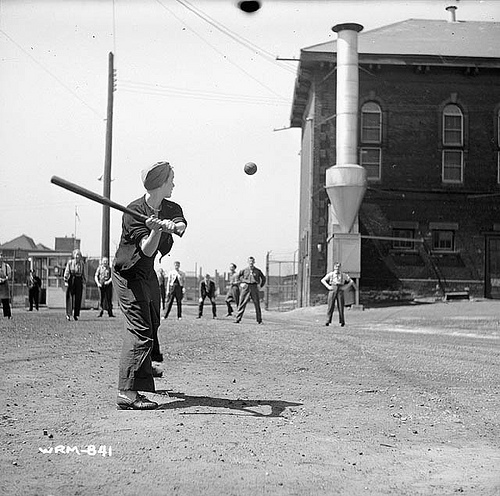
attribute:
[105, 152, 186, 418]
boy — batting, playing, playing'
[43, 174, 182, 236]
bat — held, wooden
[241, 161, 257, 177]
ball — round, small, flying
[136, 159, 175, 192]
cap — on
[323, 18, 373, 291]
pipe — tall, white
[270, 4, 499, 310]
building — brick, old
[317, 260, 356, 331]
man — standing, watching, playing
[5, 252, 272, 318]
men — watching, group, playing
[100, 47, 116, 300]
pole — tall, wooden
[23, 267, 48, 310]
police — standing, watching, onlooking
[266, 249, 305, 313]
gate — open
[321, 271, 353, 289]
shirt — white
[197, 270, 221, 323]
person — stooped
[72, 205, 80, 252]
flag pole — distant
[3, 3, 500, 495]
photograph — marked